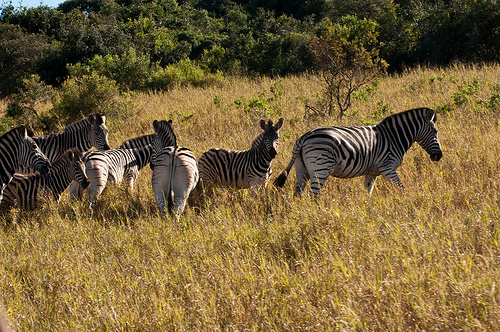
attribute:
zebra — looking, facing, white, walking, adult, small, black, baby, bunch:
[274, 106, 442, 200]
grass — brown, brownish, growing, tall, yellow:
[0, 62, 498, 332]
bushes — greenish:
[219, 14, 329, 74]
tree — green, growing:
[308, 33, 382, 119]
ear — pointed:
[425, 108, 435, 123]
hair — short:
[308, 126, 391, 161]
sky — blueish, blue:
[0, 0, 88, 21]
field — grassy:
[1, 59, 499, 331]